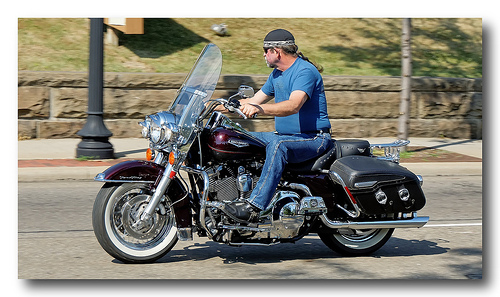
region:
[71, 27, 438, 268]
a man riding a motorcycle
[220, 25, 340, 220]
a man on a motorcycle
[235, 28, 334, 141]
a man wearing a blue shirt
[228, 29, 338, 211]
a man wearing bluejeans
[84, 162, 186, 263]
the front wheel of a motorcycle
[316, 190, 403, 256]
the rear wheel of a motorcycle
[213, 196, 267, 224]
the foot of a man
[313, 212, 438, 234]
the muffler on a motorcycle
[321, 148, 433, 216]
the saddlebag on a motorcycle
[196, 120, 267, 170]
the gas tank of a motorcycle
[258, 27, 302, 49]
this is black hat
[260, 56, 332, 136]
this is a blue t-shirt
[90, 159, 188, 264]
this is a tire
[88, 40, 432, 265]
this is a motorcycle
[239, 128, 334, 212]
this is some blue jeans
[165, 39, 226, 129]
this is a shield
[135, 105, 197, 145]
this is a light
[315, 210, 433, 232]
this is a pipe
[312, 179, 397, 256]
this is the back tire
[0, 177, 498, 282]
this is the roadway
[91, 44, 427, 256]
black and purple motor bike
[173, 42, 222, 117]
wind shield on bike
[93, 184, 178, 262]
black and white tire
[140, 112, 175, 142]
head lights on bike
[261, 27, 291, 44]
black cap on head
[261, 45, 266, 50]
sun glasses on face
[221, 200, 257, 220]
black leather riding boots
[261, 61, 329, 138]
blue cotton tee shirt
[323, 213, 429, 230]
exhaust pipe on bike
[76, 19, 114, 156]
grey metal electrical pole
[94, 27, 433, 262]
a man on a motorcycle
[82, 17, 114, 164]
a black metal pole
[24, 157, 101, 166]
red bricks on a side walk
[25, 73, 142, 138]
a brown stone wall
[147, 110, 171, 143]
a head light on a motor cycle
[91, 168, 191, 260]
a front wheel on a motor cycle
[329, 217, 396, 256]
a rear wheel of a motor cycle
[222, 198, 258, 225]
a black boot on a foot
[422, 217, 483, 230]
a white line on a road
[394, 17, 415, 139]
a gray tree trunk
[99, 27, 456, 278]
the man is riding a motorcycle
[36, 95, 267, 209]
the bike is purple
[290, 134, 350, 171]
the seat is black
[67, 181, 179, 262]
the wheel is black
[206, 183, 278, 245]
the boots are black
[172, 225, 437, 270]
a shadow on the ground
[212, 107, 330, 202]
the jeans are blue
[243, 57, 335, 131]
the shirt is blue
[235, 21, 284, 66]
the man is wearing sunglasses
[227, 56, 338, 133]
the shirt is short sleeves